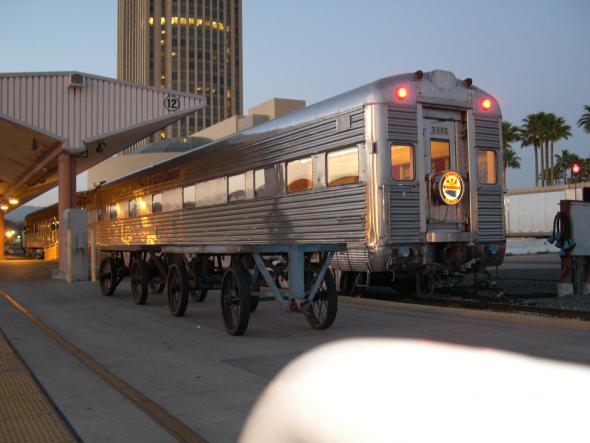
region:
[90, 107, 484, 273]
a train that is silver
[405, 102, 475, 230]
the door of a train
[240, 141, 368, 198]
the window of a train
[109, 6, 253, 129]
a building that is tall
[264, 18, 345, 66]
a sky that is blue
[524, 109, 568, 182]
a palm tree that is tall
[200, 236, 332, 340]
the wheels of a train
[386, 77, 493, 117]
two red lights on the train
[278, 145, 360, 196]
two windows on the side of the train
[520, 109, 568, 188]
palm trees are visible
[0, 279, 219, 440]
yellow line on the ground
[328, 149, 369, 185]
reflection in the window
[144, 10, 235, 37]
lights in the building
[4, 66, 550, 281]
train on the tracks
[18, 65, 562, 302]
train in the station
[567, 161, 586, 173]
red light in the distance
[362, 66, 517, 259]
the back of a train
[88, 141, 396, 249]
the side of a train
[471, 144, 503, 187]
the right back window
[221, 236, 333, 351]
the back wheels on a train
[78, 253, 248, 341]
the left side of wheels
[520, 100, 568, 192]
a tall palm tree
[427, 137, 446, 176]
glass window on the train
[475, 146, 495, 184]
glass window on the train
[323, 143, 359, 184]
glass window on the train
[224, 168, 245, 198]
glass window on the train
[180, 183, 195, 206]
glass window on the train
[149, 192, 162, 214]
glass window on the train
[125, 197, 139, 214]
glass window on the train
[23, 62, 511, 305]
grey train at a train station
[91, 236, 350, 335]
large grey carts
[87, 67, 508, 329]
silver passenger car on two steel carts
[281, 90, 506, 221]
lights lit on a rail car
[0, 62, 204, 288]
awning over a train loading platform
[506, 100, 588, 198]
palm trees beyond a wall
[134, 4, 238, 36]
upper floor of a high rise with all windows lit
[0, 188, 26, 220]
overhead lights in the awning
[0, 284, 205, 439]
a rail embedded into the pavement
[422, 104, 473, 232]
lighted sign attached to a door on the train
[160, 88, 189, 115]
the number 12 on the awning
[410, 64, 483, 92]
lights on top of the train are not lit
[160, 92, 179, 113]
Number twelve on a overhang structure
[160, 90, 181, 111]
Informational sign indicating dock number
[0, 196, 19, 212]
Lights on an overhang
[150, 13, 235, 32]
A floor lit up on a building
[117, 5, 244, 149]
A tall grey building with many windows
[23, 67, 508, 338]
A silver train at a station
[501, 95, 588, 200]
Palm trees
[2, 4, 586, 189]
A blue grey sky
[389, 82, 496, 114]
Red lights on the back of a train.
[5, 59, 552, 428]
A train at a station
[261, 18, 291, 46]
white clouds in blue sky